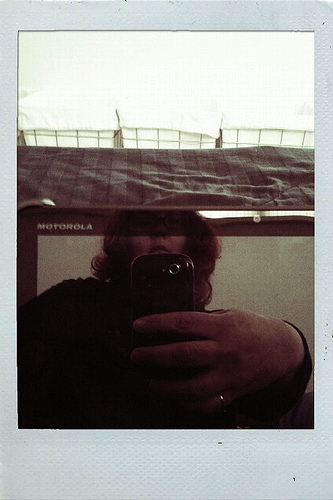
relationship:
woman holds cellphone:
[16, 207, 313, 428] [129, 249, 196, 378]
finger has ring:
[171, 392, 234, 415] [218, 393, 232, 410]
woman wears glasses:
[16, 207, 313, 428] [129, 212, 188, 233]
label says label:
[34, 221, 97, 233] [37, 222, 92, 231]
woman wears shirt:
[16, 207, 313, 428] [16, 269, 312, 427]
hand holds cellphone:
[132, 307, 307, 419] [129, 249, 196, 378]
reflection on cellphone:
[17, 206, 312, 432] [17, 198, 316, 429]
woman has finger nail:
[16, 207, 313, 428] [132, 319, 150, 336]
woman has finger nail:
[16, 207, 313, 428] [126, 347, 148, 366]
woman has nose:
[16, 207, 313, 428] [149, 223, 168, 237]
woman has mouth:
[16, 207, 313, 428] [148, 240, 176, 255]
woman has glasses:
[16, 207, 313, 428] [129, 212, 188, 233]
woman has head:
[16, 207, 313, 428] [90, 205, 221, 308]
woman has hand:
[16, 207, 313, 428] [132, 307, 307, 419]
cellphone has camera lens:
[129, 249, 196, 378] [169, 261, 183, 276]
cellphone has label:
[17, 198, 316, 429] [34, 221, 97, 233]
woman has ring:
[16, 207, 313, 428] [218, 393, 232, 410]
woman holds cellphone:
[16, 207, 313, 428] [17, 198, 316, 429]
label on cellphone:
[34, 221, 97, 233] [17, 198, 316, 429]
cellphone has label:
[129, 249, 196, 378] [34, 221, 97, 233]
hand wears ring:
[132, 307, 307, 419] [218, 393, 232, 410]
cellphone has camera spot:
[17, 198, 316, 429] [253, 212, 264, 224]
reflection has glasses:
[17, 206, 312, 432] [129, 212, 188, 233]